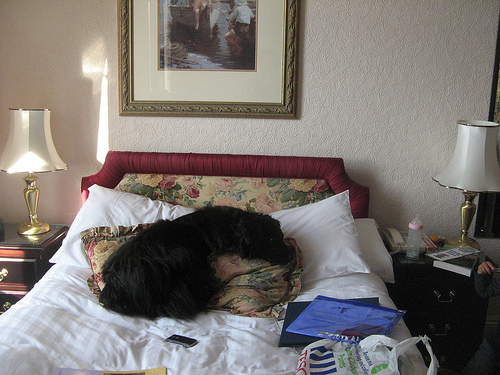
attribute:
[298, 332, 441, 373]
plastic bag — white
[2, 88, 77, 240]
lamp — large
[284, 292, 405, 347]
shirt — small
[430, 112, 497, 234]
lamp — small, bed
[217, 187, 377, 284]
pillow — large, white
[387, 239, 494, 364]
dresser — small, wood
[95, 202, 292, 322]
dog — black, large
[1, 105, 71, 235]
lamp — large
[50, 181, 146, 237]
pillow — white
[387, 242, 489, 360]
stand — cherry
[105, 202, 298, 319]
dog — black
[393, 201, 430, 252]
bottle — pink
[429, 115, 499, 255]
lamp — gold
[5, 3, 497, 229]
wall — tan